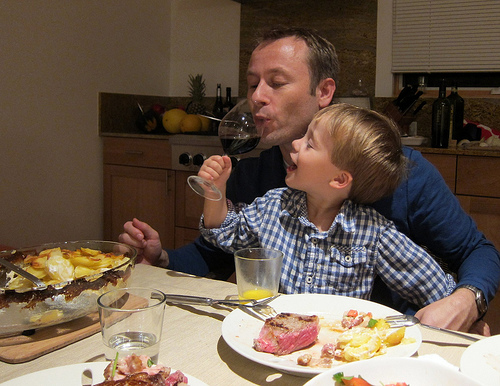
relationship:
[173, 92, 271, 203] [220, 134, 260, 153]
glass has red wine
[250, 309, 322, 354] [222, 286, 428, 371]
meat on plate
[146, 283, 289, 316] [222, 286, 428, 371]
fork on plate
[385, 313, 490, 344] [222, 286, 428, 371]
fork on plate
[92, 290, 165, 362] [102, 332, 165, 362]
glass has water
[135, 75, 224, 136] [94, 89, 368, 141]
fruit on counter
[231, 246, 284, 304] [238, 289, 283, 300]
glass has juice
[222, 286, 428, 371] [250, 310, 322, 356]
plate has meat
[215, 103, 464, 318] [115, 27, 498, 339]
child helping father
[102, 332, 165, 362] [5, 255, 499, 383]
water on table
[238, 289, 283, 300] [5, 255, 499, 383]
juice on table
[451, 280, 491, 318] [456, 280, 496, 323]
watch on wrist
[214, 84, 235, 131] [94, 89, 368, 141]
bottles on counter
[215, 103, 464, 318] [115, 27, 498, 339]
child feeding father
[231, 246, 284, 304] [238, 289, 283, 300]
glass of juice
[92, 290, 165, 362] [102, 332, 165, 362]
glass of water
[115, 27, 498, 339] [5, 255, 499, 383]
father by table